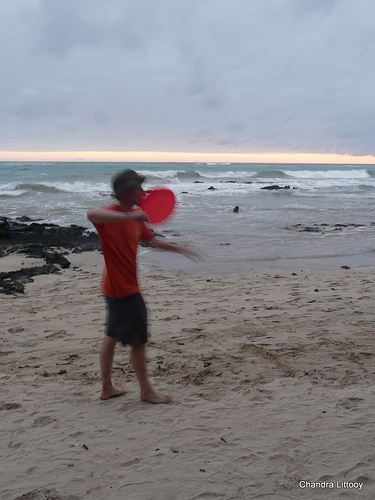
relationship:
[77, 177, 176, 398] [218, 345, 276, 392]
man standing in sand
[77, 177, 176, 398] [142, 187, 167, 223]
man throwing frisbee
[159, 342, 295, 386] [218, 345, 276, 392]
footprints are on sand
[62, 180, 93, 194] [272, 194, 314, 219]
seafoam on waves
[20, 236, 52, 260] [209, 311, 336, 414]
rocks are on beach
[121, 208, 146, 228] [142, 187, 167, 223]
hand grasping frisbee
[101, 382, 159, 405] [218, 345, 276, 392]
feet are in sand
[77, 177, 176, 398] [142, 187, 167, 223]
man playing frisbee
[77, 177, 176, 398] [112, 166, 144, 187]
man wearing hat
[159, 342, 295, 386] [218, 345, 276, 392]
footprints on top of sand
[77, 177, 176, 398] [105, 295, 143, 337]
man in shorts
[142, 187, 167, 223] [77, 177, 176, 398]
frisbee held by man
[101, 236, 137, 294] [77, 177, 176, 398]
shirt on man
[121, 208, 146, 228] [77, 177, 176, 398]
hand of man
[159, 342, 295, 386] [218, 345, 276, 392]
footprints are in sand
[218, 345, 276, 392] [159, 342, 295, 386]
sand has a lot of footprints